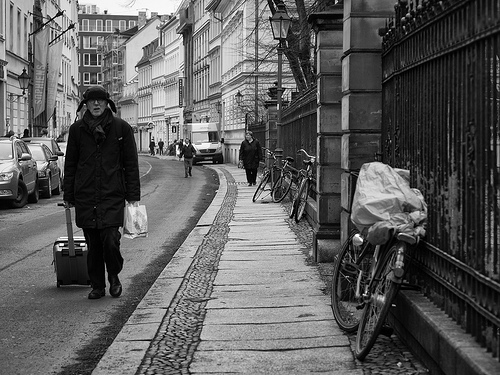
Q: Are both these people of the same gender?
A: No, they are both male and female.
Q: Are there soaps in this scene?
A: No, there are no soaps.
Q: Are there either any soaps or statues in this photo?
A: No, there are no soaps or statues.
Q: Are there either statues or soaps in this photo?
A: No, there are no soaps or statues.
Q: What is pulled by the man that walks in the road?
A: The luggage is pulled by the man.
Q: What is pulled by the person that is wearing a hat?
A: The luggage is pulled by the man.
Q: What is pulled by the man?
A: The luggage is pulled by the man.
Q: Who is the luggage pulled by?
A: The luggage is pulled by the man.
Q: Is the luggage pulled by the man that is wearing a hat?
A: Yes, the luggage is pulled by the man.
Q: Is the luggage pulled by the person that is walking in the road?
A: Yes, the luggage is pulled by the man.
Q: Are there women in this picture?
A: Yes, there is a woman.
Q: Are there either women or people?
A: Yes, there is a woman.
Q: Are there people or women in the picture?
A: Yes, there is a woman.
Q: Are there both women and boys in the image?
A: No, there is a woman but no boys.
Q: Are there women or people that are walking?
A: Yes, the woman is walking.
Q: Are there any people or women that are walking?
A: Yes, the woman is walking.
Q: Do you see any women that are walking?
A: Yes, there is a woman that is walking.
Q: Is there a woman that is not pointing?
A: Yes, there is a woman that is walking.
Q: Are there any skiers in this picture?
A: No, there are no skiers.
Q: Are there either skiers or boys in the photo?
A: No, there are no skiers or boys.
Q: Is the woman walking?
A: Yes, the woman is walking.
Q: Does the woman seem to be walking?
A: Yes, the woman is walking.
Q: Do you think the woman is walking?
A: Yes, the woman is walking.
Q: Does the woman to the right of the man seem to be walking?
A: Yes, the woman is walking.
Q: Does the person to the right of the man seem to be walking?
A: Yes, the woman is walking.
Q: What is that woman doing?
A: The woman is walking.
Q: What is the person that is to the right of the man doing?
A: The woman is walking.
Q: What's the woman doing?
A: The woman is walking.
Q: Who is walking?
A: The woman is walking.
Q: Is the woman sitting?
A: No, the woman is walking.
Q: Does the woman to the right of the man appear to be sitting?
A: No, the woman is walking.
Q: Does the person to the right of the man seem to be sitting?
A: No, the woman is walking.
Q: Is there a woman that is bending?
A: No, there is a woman but she is walking.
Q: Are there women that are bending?
A: No, there is a woman but she is walking.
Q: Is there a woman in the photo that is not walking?
A: No, there is a woman but she is walking.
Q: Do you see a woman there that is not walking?
A: No, there is a woman but she is walking.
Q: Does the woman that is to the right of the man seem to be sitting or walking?
A: The woman is walking.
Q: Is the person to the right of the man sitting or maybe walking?
A: The woman is walking.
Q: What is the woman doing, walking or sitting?
A: The woman is walking.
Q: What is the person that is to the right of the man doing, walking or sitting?
A: The woman is walking.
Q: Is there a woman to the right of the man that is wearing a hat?
A: Yes, there is a woman to the right of the man.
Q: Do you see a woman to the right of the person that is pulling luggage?
A: Yes, there is a woman to the right of the man.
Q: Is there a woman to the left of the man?
A: No, the woman is to the right of the man.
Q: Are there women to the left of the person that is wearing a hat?
A: No, the woman is to the right of the man.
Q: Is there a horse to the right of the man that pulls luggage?
A: No, there is a woman to the right of the man.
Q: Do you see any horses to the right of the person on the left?
A: No, there is a woman to the right of the man.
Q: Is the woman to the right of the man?
A: Yes, the woman is to the right of the man.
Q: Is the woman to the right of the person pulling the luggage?
A: Yes, the woman is to the right of the man.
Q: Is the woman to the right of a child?
A: No, the woman is to the right of the man.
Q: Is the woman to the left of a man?
A: No, the woman is to the right of a man.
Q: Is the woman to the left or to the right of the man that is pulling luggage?
A: The woman is to the right of the man.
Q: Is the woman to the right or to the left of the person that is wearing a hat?
A: The woman is to the right of the man.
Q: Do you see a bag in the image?
A: Yes, there is a bag.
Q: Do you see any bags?
A: Yes, there is a bag.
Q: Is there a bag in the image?
A: Yes, there is a bag.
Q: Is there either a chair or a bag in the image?
A: Yes, there is a bag.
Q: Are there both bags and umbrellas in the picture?
A: No, there is a bag but no umbrellas.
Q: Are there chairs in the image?
A: No, there are no chairs.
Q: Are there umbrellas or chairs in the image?
A: No, there are no chairs or umbrellas.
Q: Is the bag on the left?
A: Yes, the bag is on the left of the image.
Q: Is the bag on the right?
A: No, the bag is on the left of the image.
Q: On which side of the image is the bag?
A: The bag is on the left of the image.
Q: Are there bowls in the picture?
A: No, there are no bowls.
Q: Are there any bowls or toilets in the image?
A: No, there are no bowls or toilets.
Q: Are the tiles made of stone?
A: Yes, the tiles are made of stone.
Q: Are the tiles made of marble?
A: No, the tiles are made of stone.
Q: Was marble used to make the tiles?
A: No, the tiles are made of stone.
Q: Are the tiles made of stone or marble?
A: The tiles are made of stone.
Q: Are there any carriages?
A: No, there are no carriages.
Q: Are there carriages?
A: No, there are no carriages.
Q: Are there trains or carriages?
A: No, there are no carriages or trains.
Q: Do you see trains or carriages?
A: No, there are no carriages or trains.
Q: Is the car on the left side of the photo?
A: Yes, the car is on the left of the image.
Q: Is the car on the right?
A: No, the car is on the left of the image.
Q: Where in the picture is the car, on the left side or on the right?
A: The car is on the left of the image.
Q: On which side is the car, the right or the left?
A: The car is on the left of the image.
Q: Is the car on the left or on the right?
A: The car is on the left of the image.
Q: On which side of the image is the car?
A: The car is on the left of the image.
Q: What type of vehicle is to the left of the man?
A: The vehicle is a car.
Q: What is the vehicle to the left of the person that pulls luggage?
A: The vehicle is a car.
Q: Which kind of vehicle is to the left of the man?
A: The vehicle is a car.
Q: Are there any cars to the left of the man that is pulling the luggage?
A: Yes, there is a car to the left of the man.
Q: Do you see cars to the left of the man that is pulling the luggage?
A: Yes, there is a car to the left of the man.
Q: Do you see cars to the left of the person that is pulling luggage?
A: Yes, there is a car to the left of the man.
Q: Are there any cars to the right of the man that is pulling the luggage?
A: No, the car is to the left of the man.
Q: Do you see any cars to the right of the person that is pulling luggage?
A: No, the car is to the left of the man.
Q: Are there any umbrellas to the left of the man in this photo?
A: No, there is a car to the left of the man.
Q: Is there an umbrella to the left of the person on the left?
A: No, there is a car to the left of the man.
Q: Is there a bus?
A: No, there are no buses.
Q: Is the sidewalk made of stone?
A: Yes, the sidewalk is made of stone.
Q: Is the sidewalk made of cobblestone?
A: No, the sidewalk is made of stone.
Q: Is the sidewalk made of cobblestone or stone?
A: The sidewalk is made of stone.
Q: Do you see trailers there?
A: No, there are no trailers.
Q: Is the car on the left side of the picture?
A: Yes, the car is on the left of the image.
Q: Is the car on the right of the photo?
A: No, the car is on the left of the image.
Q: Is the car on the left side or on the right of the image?
A: The car is on the left of the image.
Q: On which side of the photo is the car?
A: The car is on the left of the image.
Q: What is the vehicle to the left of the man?
A: The vehicle is a car.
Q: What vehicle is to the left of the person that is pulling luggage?
A: The vehicle is a car.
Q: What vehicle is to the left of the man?
A: The vehicle is a car.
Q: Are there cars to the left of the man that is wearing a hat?
A: Yes, there is a car to the left of the man.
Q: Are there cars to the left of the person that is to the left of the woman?
A: Yes, there is a car to the left of the man.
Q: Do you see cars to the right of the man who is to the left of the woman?
A: No, the car is to the left of the man.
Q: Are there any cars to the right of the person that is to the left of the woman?
A: No, the car is to the left of the man.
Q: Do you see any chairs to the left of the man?
A: No, there is a car to the left of the man.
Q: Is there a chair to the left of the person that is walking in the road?
A: No, there is a car to the left of the man.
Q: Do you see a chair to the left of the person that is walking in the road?
A: No, there is a car to the left of the man.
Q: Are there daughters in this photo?
A: No, there are no daughters.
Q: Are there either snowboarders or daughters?
A: No, there are no daughters or snowboarders.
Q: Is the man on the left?
A: Yes, the man is on the left of the image.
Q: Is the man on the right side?
A: No, the man is on the left of the image.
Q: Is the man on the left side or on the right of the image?
A: The man is on the left of the image.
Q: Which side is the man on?
A: The man is on the left of the image.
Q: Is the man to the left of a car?
A: No, the man is to the right of a car.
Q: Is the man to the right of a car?
A: Yes, the man is to the right of a car.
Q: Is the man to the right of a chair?
A: No, the man is to the right of a car.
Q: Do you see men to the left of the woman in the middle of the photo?
A: Yes, there is a man to the left of the woman.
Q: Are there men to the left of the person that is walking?
A: Yes, there is a man to the left of the woman.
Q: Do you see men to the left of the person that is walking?
A: Yes, there is a man to the left of the woman.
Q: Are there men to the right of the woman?
A: No, the man is to the left of the woman.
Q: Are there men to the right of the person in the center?
A: No, the man is to the left of the woman.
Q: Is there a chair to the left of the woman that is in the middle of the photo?
A: No, there is a man to the left of the woman.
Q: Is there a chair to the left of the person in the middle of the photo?
A: No, there is a man to the left of the woman.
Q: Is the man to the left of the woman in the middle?
A: Yes, the man is to the left of the woman.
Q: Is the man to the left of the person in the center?
A: Yes, the man is to the left of the woman.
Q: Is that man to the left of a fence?
A: No, the man is to the left of the woman.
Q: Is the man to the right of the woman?
A: No, the man is to the left of the woman.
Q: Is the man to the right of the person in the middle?
A: No, the man is to the left of the woman.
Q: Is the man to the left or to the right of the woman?
A: The man is to the left of the woman.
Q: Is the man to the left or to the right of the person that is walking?
A: The man is to the left of the woman.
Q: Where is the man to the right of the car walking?
A: The man is walking in the road.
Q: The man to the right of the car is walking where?
A: The man is walking in the road.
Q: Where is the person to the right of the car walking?
A: The man is walking in the road.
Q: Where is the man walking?
A: The man is walking in the road.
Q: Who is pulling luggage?
A: The man is pulling luggage.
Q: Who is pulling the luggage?
A: The man is pulling luggage.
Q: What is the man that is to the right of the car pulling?
A: The man is pulling luggage.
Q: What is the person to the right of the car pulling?
A: The man is pulling luggage.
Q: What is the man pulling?
A: The man is pulling luggage.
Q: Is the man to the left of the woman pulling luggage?
A: Yes, the man is pulling luggage.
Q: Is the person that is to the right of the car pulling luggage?
A: Yes, the man is pulling luggage.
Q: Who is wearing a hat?
A: The man is wearing a hat.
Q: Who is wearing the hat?
A: The man is wearing a hat.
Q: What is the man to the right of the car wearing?
A: The man is wearing a hat.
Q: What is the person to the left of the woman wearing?
A: The man is wearing a hat.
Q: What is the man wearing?
A: The man is wearing a hat.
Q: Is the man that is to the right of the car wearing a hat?
A: Yes, the man is wearing a hat.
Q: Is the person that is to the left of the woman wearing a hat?
A: Yes, the man is wearing a hat.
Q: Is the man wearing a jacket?
A: No, the man is wearing a hat.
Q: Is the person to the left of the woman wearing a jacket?
A: No, the man is wearing a hat.